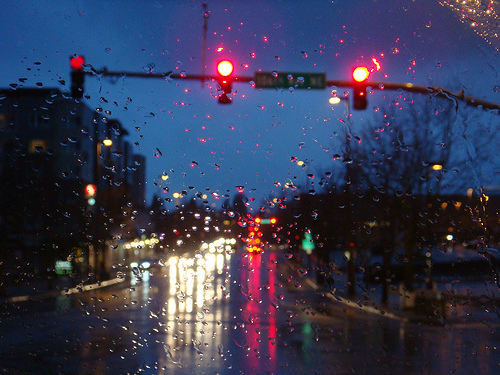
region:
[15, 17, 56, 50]
white clouds in blue sky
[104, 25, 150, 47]
white clouds in blue sky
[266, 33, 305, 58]
white clouds in blue sky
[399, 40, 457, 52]
white clouds in blue sky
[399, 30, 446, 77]
white clouds in blue sky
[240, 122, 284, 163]
white clouds in blue sky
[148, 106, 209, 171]
white clouds in blue sky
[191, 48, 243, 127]
red signal light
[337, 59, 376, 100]
red light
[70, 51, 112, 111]
red traffic light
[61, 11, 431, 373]
rain drops on a windshield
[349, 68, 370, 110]
a traffic light on red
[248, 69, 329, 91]
a green street sign with white letters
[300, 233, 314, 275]
a green street sign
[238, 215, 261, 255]
cars at a stop light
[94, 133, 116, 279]
a street lamp post that is turned on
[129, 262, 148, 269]
a pair of headlights turned on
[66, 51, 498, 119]
a long traffic stop light post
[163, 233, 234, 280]
a lot of cars driving with headlights on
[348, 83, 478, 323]
a base tree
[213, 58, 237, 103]
Traffic light with lit red stop light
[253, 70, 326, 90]
Green street sign on traffic pole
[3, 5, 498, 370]
Raindrops sitting on glass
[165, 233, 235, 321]
Headlights of cars in the distance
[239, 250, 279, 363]
Light reflecting off of wet pavement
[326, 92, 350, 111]
Lit street light on pole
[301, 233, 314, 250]
Green sign relfecting light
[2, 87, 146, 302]
Building in the background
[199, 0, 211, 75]
Traffic camera on top of light pole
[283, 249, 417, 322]
Curb on the side of the road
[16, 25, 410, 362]
it is raining on the camera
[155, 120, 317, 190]
the sky is dark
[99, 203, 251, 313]
cars driving down the road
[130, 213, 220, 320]
cars have their lights on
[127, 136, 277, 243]
rain is on the camera lens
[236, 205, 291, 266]
stop light on the road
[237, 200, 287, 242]
the stop light is red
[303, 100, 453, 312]
trees next tot he road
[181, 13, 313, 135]
red stop light in the air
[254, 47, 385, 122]
street sign in the road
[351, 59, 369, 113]
traffic light turned red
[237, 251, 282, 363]
reflection of the break lights in the street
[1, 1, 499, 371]
rain drops on a wind shield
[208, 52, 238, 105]
a red traffic light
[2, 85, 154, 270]
a large building on the left side of the street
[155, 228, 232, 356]
street lights reflecting on the street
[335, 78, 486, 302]
small trees with now leaves on the right side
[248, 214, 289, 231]
street lights turned red in the distance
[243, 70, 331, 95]
green street sign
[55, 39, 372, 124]
three traffic lights turned red